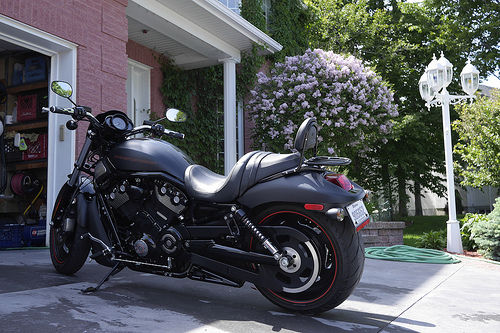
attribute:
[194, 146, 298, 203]
seat — black, leather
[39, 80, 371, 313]
motorcycle — black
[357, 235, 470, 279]
hose — green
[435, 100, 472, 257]
lamp post — white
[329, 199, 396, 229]
license plate — bike's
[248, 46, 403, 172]
lilac bush — purple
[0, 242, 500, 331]
driveway — concrete